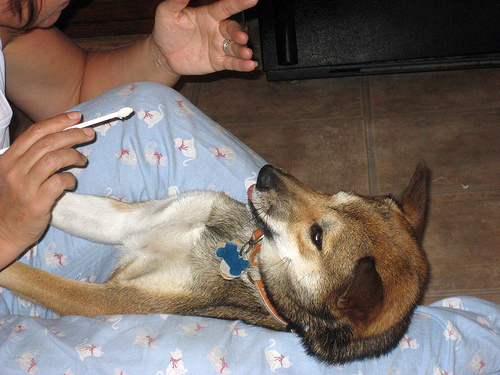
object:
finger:
[217, 19, 249, 45]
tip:
[244, 183, 257, 207]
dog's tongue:
[246, 183, 256, 202]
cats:
[136, 104, 165, 129]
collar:
[215, 228, 298, 333]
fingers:
[27, 147, 89, 186]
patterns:
[209, 57, 499, 279]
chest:
[123, 198, 236, 295]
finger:
[222, 38, 253, 60]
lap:
[31, 80, 496, 373]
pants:
[1, 83, 498, 372]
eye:
[308, 223, 324, 252]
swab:
[0, 106, 134, 155]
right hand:
[0, 110, 97, 248]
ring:
[222, 39, 232, 57]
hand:
[149, 0, 260, 77]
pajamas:
[0, 80, 494, 371]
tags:
[215, 238, 251, 281]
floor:
[439, 158, 498, 299]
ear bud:
[62, 105, 134, 132]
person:
[1, 0, 498, 374]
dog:
[0, 156, 430, 369]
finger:
[224, 56, 259, 72]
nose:
[251, 155, 288, 194]